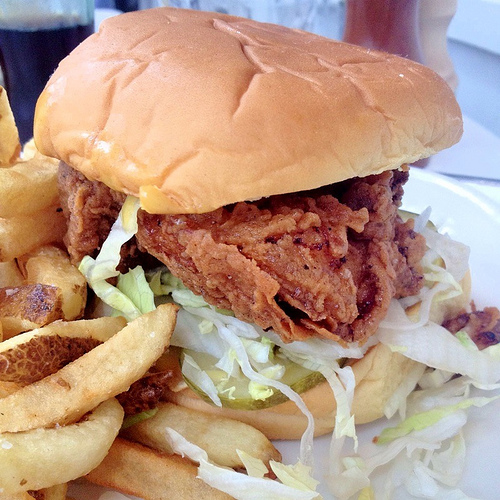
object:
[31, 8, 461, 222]
bun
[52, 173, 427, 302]
chicken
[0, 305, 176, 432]
fries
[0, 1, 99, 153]
cup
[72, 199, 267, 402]
lettuce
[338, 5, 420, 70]
bottle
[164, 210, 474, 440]
bread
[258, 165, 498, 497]
plate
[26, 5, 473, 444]
sandwich